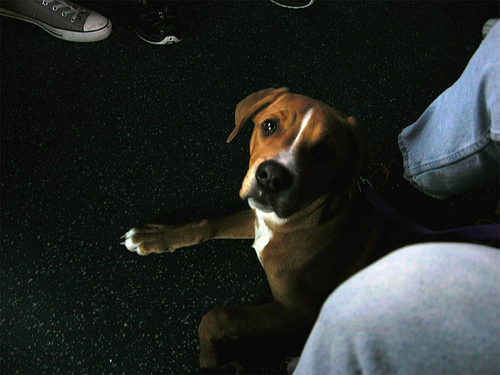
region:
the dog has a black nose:
[250, 156, 301, 203]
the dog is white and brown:
[112, 83, 442, 373]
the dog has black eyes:
[256, 112, 285, 148]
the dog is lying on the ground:
[106, 82, 461, 373]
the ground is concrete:
[1, 0, 498, 373]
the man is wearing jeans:
[288, 18, 498, 372]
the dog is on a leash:
[346, 161, 499, 256]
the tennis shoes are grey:
[0, 0, 116, 51]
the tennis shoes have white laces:
[6, 0, 118, 43]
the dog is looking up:
[113, 80, 498, 373]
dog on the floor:
[98, 73, 413, 368]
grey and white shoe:
[0, 0, 131, 45]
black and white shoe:
[118, 0, 203, 58]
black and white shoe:
[256, 0, 339, 12]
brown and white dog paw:
[107, 210, 177, 262]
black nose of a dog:
[251, 155, 298, 192]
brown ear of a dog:
[207, 75, 292, 152]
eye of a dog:
[251, 109, 289, 149]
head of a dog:
[205, 80, 395, 233]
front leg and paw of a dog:
[112, 199, 266, 267]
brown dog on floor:
[159, 91, 355, 316]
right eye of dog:
[251, 120, 278, 139]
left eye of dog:
[309, 143, 335, 168]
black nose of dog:
[240, 155, 292, 204]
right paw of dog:
[124, 217, 191, 287]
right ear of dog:
[209, 80, 281, 142]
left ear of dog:
[336, 118, 366, 165]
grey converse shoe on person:
[41, 0, 104, 56]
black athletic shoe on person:
[139, 12, 184, 64]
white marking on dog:
[295, 100, 304, 158]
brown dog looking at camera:
[101, 59, 391, 373]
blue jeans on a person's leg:
[384, 11, 494, 230]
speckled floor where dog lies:
[7, 83, 115, 342]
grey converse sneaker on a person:
[6, 1, 118, 46]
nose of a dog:
[253, 159, 296, 193]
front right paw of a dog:
[118, 217, 157, 271]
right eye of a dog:
[253, 111, 285, 145]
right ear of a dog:
[219, 71, 261, 147]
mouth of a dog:
[237, 191, 282, 218]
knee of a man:
[314, 230, 471, 367]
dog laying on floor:
[104, 70, 392, 365]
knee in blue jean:
[319, 235, 479, 351]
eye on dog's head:
[253, 105, 287, 143]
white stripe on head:
[288, 100, 323, 153]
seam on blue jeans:
[438, 105, 491, 177]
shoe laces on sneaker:
[52, 1, 85, 26]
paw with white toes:
[114, 217, 165, 265]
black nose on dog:
[251, 157, 298, 202]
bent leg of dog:
[188, 291, 257, 369]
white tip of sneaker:
[147, 24, 192, 52]